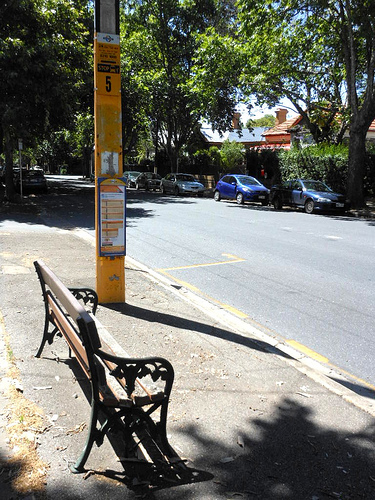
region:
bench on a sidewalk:
[7, 253, 253, 494]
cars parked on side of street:
[165, 143, 351, 218]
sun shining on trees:
[150, 14, 361, 102]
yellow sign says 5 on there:
[96, 29, 124, 302]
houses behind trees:
[192, 121, 373, 171]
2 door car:
[212, 171, 272, 218]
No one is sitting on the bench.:
[8, 258, 228, 487]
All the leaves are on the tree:
[1, 0, 350, 118]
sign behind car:
[2, 137, 51, 202]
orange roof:
[261, 109, 303, 150]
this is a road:
[199, 216, 289, 284]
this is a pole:
[92, 3, 126, 282]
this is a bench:
[34, 290, 119, 419]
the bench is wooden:
[42, 271, 63, 298]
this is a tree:
[137, 6, 201, 122]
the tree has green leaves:
[202, 46, 228, 68]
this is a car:
[215, 174, 262, 202]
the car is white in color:
[181, 181, 192, 189]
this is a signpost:
[16, 137, 22, 201]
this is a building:
[265, 117, 297, 141]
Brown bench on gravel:
[19, 252, 188, 417]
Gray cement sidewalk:
[109, 312, 271, 421]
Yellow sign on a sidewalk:
[74, 147, 167, 273]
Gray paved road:
[154, 194, 306, 308]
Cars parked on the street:
[129, 163, 349, 214]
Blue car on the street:
[196, 171, 286, 204]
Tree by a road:
[131, 56, 225, 202]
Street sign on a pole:
[14, 135, 51, 208]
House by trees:
[249, 102, 312, 149]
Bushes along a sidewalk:
[198, 143, 372, 183]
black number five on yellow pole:
[95, 69, 125, 116]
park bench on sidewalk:
[31, 260, 186, 487]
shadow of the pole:
[61, 298, 374, 397]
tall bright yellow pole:
[83, 6, 141, 311]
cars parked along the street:
[126, 163, 354, 224]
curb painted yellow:
[184, 278, 335, 385]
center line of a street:
[267, 214, 355, 271]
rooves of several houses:
[194, 103, 353, 154]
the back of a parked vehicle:
[5, 151, 58, 207]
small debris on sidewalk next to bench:
[60, 418, 254, 488]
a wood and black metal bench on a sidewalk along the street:
[20, 254, 190, 475]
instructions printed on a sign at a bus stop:
[93, 174, 130, 257]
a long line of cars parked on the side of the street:
[131, 168, 350, 214]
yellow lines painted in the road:
[151, 244, 247, 304]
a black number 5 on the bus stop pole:
[98, 70, 119, 95]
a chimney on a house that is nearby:
[270, 104, 294, 123]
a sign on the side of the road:
[14, 134, 29, 198]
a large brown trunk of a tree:
[324, 29, 374, 200]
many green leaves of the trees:
[128, 9, 306, 114]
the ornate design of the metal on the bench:
[107, 361, 170, 385]